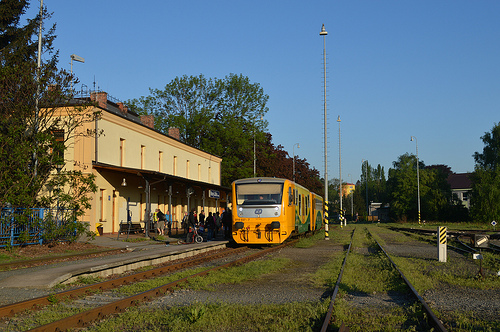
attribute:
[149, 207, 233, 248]
people — waiting, standing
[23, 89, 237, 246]
station — train, old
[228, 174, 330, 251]
train — green, commuter, yellow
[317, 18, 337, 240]
pole — yellow, black, long, electric, tall, metal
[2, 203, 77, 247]
fence — blue, metal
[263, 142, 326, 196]
trees — red fern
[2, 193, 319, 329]
tracks — big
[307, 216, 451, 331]
tracks — big